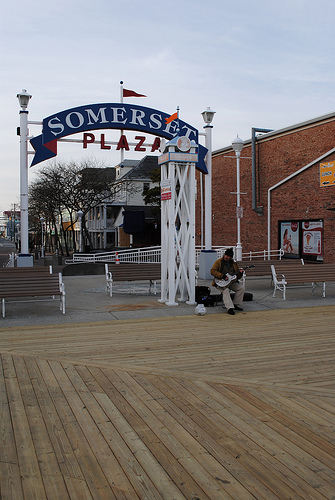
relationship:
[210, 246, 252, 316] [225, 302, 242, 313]
man wearing shoes